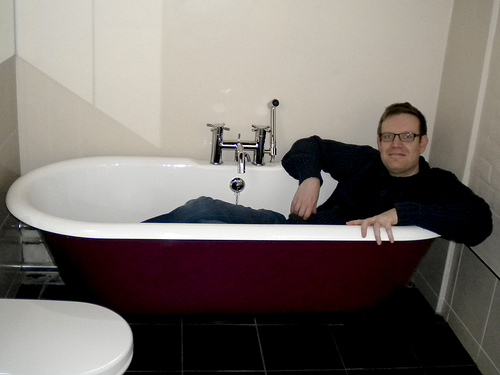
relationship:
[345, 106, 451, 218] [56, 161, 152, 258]
man in tub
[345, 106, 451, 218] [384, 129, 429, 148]
man wearing glasses